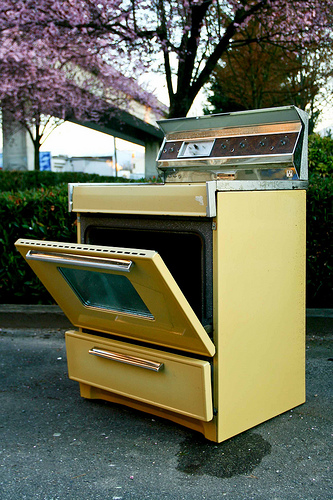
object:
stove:
[14, 104, 309, 445]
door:
[14, 238, 216, 357]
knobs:
[163, 149, 167, 154]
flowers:
[3, 0, 154, 125]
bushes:
[1, 169, 77, 307]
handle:
[25, 249, 134, 274]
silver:
[67, 104, 312, 217]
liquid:
[175, 426, 273, 479]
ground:
[0, 327, 333, 500]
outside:
[2, 0, 332, 500]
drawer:
[65, 329, 214, 423]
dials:
[159, 131, 300, 159]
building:
[0, 19, 170, 184]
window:
[0, 108, 145, 179]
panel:
[158, 132, 298, 160]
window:
[58, 267, 154, 322]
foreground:
[0, 180, 224, 500]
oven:
[68, 184, 215, 360]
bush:
[306, 127, 333, 281]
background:
[0, 0, 332, 308]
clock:
[177, 137, 216, 158]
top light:
[195, 106, 294, 118]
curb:
[0, 296, 80, 330]